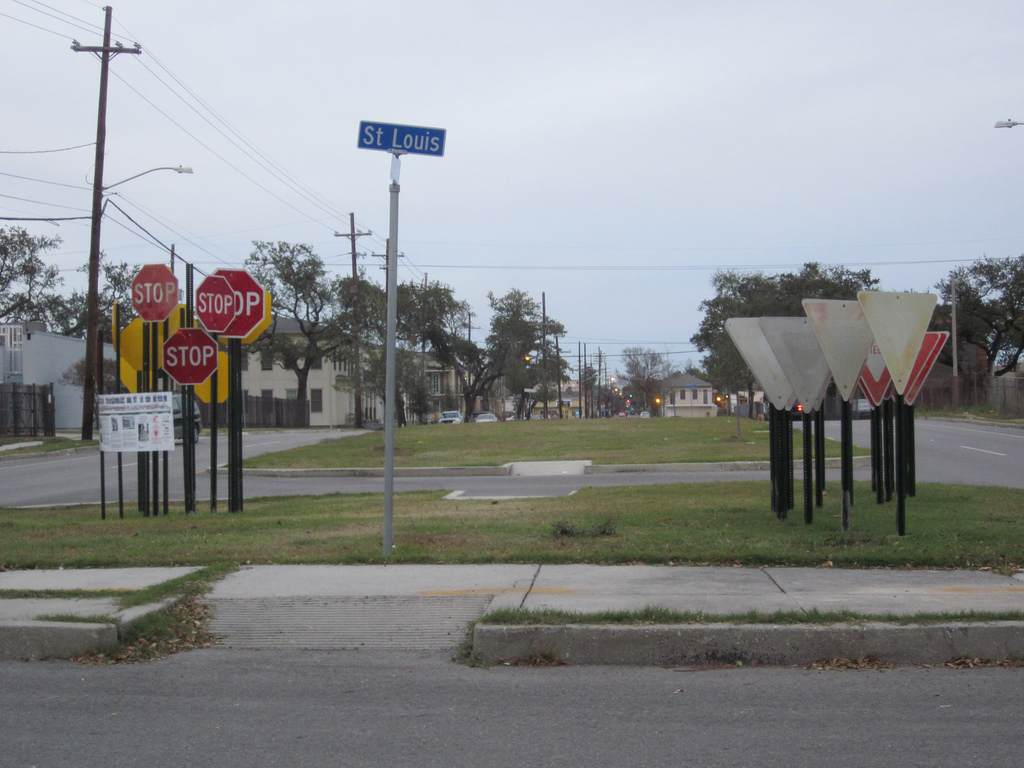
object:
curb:
[469, 619, 1020, 666]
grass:
[477, 603, 1022, 625]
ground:
[0, 417, 1024, 768]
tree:
[328, 276, 386, 431]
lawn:
[214, 415, 871, 476]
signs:
[725, 291, 946, 541]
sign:
[195, 275, 234, 333]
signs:
[120, 263, 273, 402]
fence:
[243, 389, 311, 428]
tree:
[244, 240, 339, 428]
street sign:
[358, 121, 445, 557]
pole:
[383, 147, 399, 561]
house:
[659, 375, 719, 419]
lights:
[611, 377, 721, 407]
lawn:
[0, 483, 1021, 574]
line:
[420, 589, 577, 594]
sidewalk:
[0, 564, 1021, 616]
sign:
[356, 121, 446, 159]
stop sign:
[132, 263, 179, 321]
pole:
[139, 317, 171, 518]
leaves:
[74, 603, 206, 664]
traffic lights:
[655, 396, 723, 403]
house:
[243, 315, 356, 426]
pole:
[118, 245, 246, 521]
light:
[715, 395, 723, 403]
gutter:
[47, 593, 220, 665]